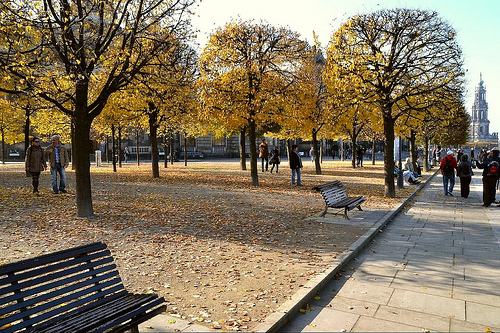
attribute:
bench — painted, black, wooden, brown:
[0, 240, 173, 333]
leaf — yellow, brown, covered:
[1, 158, 438, 333]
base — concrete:
[301, 197, 394, 232]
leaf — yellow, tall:
[322, 8, 463, 205]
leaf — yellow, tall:
[191, 12, 331, 192]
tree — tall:
[3, 2, 190, 221]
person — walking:
[457, 152, 476, 200]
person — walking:
[437, 148, 459, 198]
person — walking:
[476, 146, 499, 205]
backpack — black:
[482, 159, 499, 182]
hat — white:
[444, 148, 457, 157]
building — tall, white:
[463, 71, 499, 157]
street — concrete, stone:
[262, 157, 499, 333]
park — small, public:
[2, 2, 497, 333]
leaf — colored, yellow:
[325, 23, 347, 38]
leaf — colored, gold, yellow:
[327, 48, 335, 54]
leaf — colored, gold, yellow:
[326, 78, 335, 89]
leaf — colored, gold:
[369, 122, 382, 131]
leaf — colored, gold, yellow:
[322, 103, 331, 109]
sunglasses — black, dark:
[31, 137, 42, 147]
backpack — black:
[443, 157, 455, 177]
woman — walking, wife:
[24, 135, 48, 196]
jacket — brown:
[25, 136, 50, 180]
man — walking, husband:
[45, 132, 72, 196]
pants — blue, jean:
[48, 159, 70, 197]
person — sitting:
[392, 157, 420, 187]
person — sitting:
[405, 154, 415, 181]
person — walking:
[286, 141, 308, 188]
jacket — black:
[473, 153, 500, 184]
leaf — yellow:
[209, 37, 220, 45]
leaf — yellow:
[17, 57, 26, 70]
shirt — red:
[436, 150, 459, 175]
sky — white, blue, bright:
[3, 2, 496, 132]